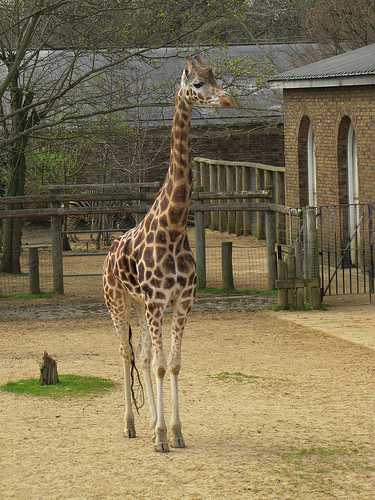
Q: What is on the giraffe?
A: The spots are on the giraffe.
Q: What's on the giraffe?
A: The spots are on the giraffe.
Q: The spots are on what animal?
A: The spots are on the giraffe.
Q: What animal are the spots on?
A: The spots are on the giraffe.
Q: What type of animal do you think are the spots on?
A: The spots are on the giraffe.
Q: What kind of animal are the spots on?
A: The spots are on the giraffe.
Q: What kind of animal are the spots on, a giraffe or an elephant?
A: The spots are on a giraffe.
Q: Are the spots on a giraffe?
A: Yes, the spots are on a giraffe.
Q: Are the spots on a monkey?
A: No, the spots are on a giraffe.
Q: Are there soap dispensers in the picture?
A: No, there are no soap dispensers.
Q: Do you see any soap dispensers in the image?
A: No, there are no soap dispensers.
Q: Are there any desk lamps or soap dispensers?
A: No, there are no soap dispensers or desk lamps.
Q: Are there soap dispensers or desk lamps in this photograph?
A: No, there are no soap dispensers or desk lamps.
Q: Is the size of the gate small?
A: Yes, the gate is small.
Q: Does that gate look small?
A: Yes, the gate is small.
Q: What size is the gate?
A: The gate is small.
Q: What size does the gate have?
A: The gate has small size.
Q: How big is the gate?
A: The gate is small.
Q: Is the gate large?
A: No, the gate is small.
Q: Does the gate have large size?
A: No, the gate is small.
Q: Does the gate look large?
A: No, the gate is small.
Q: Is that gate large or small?
A: The gate is small.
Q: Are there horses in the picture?
A: No, there are no horses.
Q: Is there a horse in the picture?
A: No, there are no horses.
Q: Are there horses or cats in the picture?
A: No, there are no horses or cats.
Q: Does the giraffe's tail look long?
A: Yes, the tail is long.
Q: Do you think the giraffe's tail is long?
A: Yes, the tail is long.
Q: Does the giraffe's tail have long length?
A: Yes, the tail is long.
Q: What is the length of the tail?
A: The tail is long.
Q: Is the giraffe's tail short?
A: No, the tail is long.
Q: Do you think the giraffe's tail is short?
A: No, the tail is long.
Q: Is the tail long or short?
A: The tail is long.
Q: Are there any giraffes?
A: Yes, there is a giraffe.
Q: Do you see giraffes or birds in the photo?
A: Yes, there is a giraffe.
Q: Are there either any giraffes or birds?
A: Yes, there is a giraffe.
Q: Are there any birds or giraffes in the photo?
A: Yes, there is a giraffe.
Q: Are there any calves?
A: No, there are no calves.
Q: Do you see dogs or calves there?
A: No, there are no calves or dogs.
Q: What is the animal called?
A: The animal is a giraffe.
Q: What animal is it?
A: The animal is a giraffe.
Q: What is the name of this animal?
A: This is a giraffe.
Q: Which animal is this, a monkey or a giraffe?
A: This is a giraffe.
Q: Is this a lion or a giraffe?
A: This is a giraffe.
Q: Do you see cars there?
A: No, there are no cars.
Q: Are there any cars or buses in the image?
A: No, there are no cars or buses.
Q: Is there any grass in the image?
A: Yes, there is grass.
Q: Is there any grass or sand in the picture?
A: Yes, there is grass.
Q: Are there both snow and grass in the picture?
A: No, there is grass but no snow.